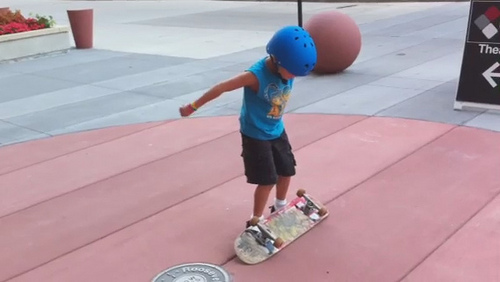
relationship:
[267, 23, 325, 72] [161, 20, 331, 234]
helmet on boy